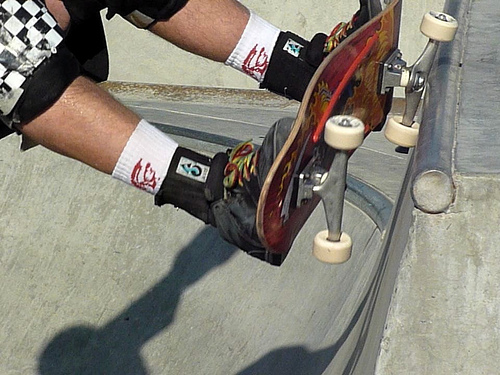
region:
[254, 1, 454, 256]
the wooden skateboard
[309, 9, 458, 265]
the wheels under the skateboard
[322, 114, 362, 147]
the wheel under the skateboard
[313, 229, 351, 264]
the wheel under the skateboard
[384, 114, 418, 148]
the wheel under the skateboard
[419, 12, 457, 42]
the wheel under the skateboard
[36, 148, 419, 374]
the shadow on the ground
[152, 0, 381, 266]
the shoes on the man's feet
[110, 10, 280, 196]
the socks on the man's feet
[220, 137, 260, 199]
the shoelaces on the man's shoe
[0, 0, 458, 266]
Person is on a skateboard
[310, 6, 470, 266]
Skateboard has four wheels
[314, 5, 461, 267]
Skateboard has four white wheels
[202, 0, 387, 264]
Person is wearing shoes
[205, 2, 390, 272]
Person is wearing black shoes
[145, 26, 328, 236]
Person is wearing ankle braces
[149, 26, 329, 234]
Person is wearing black ankle braces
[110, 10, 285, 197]
Person is wearing socks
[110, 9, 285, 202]
Person is wearing white socks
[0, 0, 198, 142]
Person is wearing kneepads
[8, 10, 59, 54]
black and white checkered design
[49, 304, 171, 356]
shadow of man on pavement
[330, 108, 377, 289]
white and silver skateboard wheels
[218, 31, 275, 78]
white socks with warriors logo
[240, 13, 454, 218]
red decorated skateboard with white wheels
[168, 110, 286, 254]
black shoes with red and green laces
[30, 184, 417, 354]
cement pavement for skatepark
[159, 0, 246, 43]
dark hairy legs on man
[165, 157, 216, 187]
arrow logog on black shoes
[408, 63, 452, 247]
silver round rail on top of cement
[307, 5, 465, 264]
white wheels on bottom of skateboard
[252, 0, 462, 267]
red and yellow skateboard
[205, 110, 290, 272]
black sneaker with red and green shoelaces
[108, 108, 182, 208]
white sock with red design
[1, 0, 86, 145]
kneepad on knee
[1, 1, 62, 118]
balck and white checker pattern on kneepad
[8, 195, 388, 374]
black shadow on grey wall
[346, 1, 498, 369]
grey concrete curb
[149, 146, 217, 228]
black material wrapped around ankle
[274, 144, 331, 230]
silver bolt on bottom of skateboard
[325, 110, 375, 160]
wheel of a skate board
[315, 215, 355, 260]
wheel of a skate board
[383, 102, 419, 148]
wheel of a skate board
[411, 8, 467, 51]
wheel of a skate board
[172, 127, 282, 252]
man wearing black shoes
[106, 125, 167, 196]
man wearing white socks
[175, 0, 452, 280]
man riding a skate board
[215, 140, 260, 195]
shoe strings in tennis shoes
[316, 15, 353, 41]
string inside tennis shoes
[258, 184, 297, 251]
board of a skate board